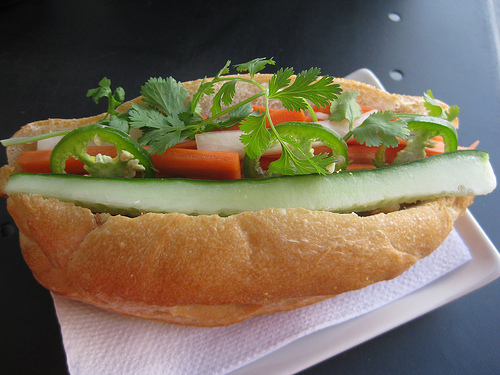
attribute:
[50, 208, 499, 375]
napkin — white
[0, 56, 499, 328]
sandwhich — vegtable, veggie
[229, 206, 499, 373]
plate — white, small, ceramic, rectangular, square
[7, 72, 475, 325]
bread — golden, white, a sandwich roll, cut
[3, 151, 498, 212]
pickle — green, cut, long, sliced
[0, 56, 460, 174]
cilantro — fresh, sprigs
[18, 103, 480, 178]
carrots — sliced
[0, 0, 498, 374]
table — black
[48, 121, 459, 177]
jalepeno peppers — sliced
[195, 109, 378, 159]
onion — long, sliced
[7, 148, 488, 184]
peel — green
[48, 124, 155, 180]
jalepeno pepper — sliced